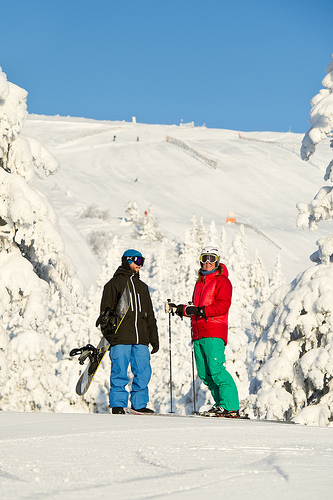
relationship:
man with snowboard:
[88, 239, 152, 327] [43, 275, 144, 390]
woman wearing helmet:
[188, 247, 232, 290] [198, 247, 222, 255]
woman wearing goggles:
[188, 247, 232, 290] [198, 255, 221, 264]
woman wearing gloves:
[188, 247, 232, 290] [159, 299, 207, 320]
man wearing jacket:
[88, 239, 152, 327] [92, 272, 242, 346]